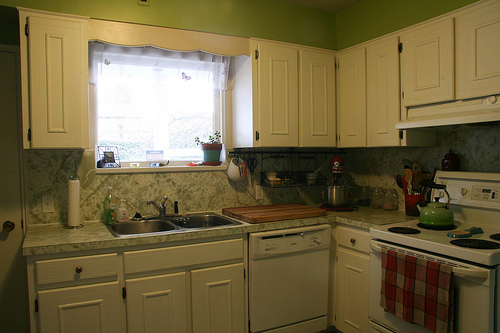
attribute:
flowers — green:
[192, 130, 223, 143]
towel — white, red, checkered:
[379, 240, 451, 330]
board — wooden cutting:
[231, 198, 336, 226]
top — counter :
[334, 202, 404, 232]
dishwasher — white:
[260, 224, 335, 328]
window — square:
[86, 43, 226, 163]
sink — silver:
[102, 205, 236, 239]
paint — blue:
[205, 150, 219, 165]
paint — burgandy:
[202, 143, 222, 149]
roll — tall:
[63, 175, 83, 232]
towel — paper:
[70, 186, 76, 222]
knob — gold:
[72, 261, 86, 278]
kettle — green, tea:
[410, 179, 457, 229]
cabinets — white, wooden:
[247, 10, 482, 147]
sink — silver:
[106, 211, 263, 236]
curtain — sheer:
[93, 43, 227, 162]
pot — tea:
[411, 180, 456, 230]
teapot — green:
[410, 180, 460, 227]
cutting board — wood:
[220, 202, 326, 222]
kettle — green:
[412, 177, 458, 225]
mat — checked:
[377, 246, 452, 322]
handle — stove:
[370, 240, 482, 282]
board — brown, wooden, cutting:
[221, 202, 327, 222]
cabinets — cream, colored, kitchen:
[21, 224, 331, 324]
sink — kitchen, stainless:
[171, 208, 243, 229]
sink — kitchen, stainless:
[110, 217, 181, 233]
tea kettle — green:
[416, 181, 456, 230]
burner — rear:
[414, 219, 459, 233]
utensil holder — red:
[403, 191, 421, 216]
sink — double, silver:
[102, 200, 238, 237]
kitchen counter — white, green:
[15, 213, 111, 257]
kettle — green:
[410, 180, 455, 234]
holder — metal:
[65, 173, 81, 231]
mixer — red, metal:
[312, 153, 353, 218]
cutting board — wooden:
[225, 200, 326, 223]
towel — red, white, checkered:
[377, 243, 457, 331]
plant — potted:
[195, 130, 224, 168]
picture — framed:
[99, 148, 120, 175]